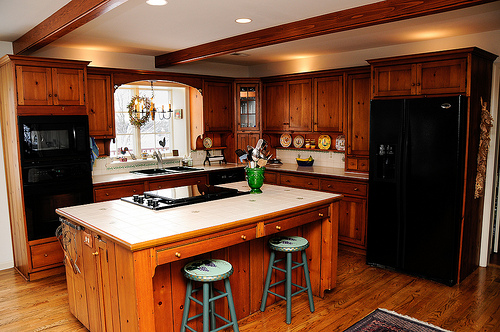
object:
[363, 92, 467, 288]
black refridgerator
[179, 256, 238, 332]
bar stool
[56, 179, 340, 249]
counter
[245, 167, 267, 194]
container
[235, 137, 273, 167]
utensils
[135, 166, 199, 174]
sink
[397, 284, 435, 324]
ground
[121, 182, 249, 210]
stove top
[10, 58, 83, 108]
cabinet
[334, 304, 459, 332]
carpet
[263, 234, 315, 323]
stool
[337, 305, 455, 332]
rug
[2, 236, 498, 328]
floor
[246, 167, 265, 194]
vase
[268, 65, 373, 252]
brown cabinets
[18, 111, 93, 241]
black oven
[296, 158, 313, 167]
basket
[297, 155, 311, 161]
banana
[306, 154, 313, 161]
banana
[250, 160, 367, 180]
counter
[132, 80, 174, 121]
candle holder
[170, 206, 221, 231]
lamp post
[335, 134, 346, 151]
plates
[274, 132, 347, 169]
shelf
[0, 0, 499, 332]
kitchen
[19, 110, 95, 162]
microwave